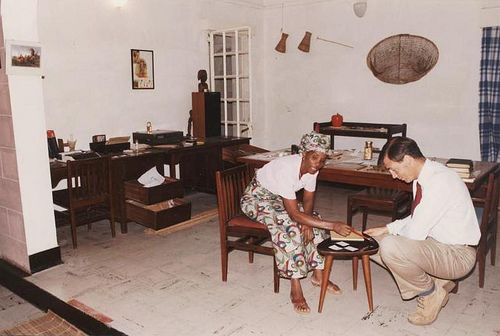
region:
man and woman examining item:
[239, 122, 491, 328]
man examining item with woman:
[358, 134, 489, 333]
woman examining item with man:
[234, 127, 368, 312]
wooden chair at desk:
[61, 156, 125, 250]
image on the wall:
[125, 45, 159, 93]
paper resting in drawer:
[136, 162, 166, 190]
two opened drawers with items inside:
[125, 164, 198, 230]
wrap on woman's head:
[297, 128, 339, 156]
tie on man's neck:
[409, 182, 424, 217]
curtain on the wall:
[472, 19, 499, 161]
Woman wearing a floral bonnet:
[287, 128, 343, 182]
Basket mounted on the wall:
[359, 30, 449, 90]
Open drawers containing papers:
[120, 164, 198, 233]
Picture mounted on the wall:
[120, 41, 167, 97]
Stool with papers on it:
[306, 221, 383, 318]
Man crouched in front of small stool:
[359, 130, 491, 330]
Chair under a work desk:
[52, 143, 127, 249]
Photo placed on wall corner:
[0, 33, 58, 84]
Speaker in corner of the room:
[186, 78, 229, 149]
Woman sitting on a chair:
[208, 131, 343, 281]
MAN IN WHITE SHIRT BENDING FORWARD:
[374, 141, 499, 293]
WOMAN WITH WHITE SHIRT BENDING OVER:
[247, 80, 347, 282]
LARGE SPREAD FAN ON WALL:
[361, 27, 449, 86]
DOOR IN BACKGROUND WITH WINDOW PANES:
[194, 37, 258, 174]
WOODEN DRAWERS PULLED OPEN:
[132, 144, 190, 238]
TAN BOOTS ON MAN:
[386, 280, 458, 317]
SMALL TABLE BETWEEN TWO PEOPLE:
[308, 212, 378, 289]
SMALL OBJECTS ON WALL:
[297, 23, 315, 57]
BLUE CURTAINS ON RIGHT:
[445, 30, 498, 123]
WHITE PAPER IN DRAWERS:
[135, 160, 176, 190]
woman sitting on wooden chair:
[213, 116, 336, 301]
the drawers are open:
[121, 146, 212, 243]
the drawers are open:
[212, 132, 283, 182]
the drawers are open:
[219, 108, 291, 220]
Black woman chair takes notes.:
[216, 122, 373, 322]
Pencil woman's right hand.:
[307, 215, 378, 242]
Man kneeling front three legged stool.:
[367, 137, 486, 324]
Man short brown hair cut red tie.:
[377, 127, 459, 216]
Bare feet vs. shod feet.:
[285, 256, 465, 327]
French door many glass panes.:
[203, 21, 262, 144]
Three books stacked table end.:
[433, 152, 498, 196]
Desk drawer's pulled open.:
[105, 140, 199, 236]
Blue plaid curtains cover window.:
[470, 7, 498, 182]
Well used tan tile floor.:
[89, 220, 271, 329]